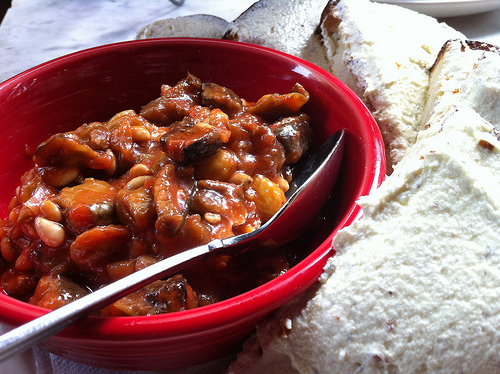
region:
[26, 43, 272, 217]
A red bowl filled with food.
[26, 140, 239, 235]
Food of choice appears to be chili.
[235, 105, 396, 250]
A silver spoon inside a red bowl.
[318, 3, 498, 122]
Slices of bread next to red bowl.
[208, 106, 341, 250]
A silver spoon resting ontop of food.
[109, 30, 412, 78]
A red bowl with white bread for contrast.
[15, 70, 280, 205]
A bowl filled with comfort food.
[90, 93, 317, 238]
A bowl filled with food that is not consumed.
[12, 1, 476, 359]
a spoon in a bowl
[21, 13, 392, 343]
a red bowl with food in it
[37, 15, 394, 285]
a bowl of food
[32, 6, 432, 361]
beans in a bowl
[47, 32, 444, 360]
a silver spoon in a bowl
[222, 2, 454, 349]
food on the side of a bowl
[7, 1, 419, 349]
a bowl on a table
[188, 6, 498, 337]
lots of bread near a bowl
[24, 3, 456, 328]
a bean soup in a bowl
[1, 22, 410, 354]
MEAT DISH IN RED BOWL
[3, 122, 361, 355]
LARGE SPOON IN MAIN DISH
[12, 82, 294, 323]
BEEF STEW IN BOWL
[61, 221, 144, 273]
CARROT IN STEW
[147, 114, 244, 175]
MEAT IN STEW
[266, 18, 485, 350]
MULTIPLE BREAD ITEMS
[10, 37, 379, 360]
GLASS BOWL FOR SERVING FOOD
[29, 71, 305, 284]
SAUCE IN STEW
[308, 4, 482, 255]
SANDWICHES CUT INTO TRIANGLES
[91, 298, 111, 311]
part of a spoon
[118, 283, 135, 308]
edge of a spoon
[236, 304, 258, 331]
part of a bowl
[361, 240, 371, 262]
part of a cloth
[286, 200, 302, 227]
part of a spoon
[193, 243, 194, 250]
edge of a spoon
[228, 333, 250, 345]
side of a bowl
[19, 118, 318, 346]
the metal silver spoon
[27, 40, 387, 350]
the deep red bowl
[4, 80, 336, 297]
the chili in the red bowl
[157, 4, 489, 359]
the bread laying next to the bowl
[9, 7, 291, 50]
the table the stuff is sitting on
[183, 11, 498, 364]
the toasted bread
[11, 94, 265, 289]
the vegtables in the chili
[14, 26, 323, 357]
the bowl and spoon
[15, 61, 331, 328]
the food in the red bowl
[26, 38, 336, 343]
the round bowl with food in it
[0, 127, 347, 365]
A long silver spoon.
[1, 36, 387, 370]
A round red bowl.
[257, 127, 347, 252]
An oval silver spoon end.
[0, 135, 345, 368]
spoon resting on its side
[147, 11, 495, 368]
slices of bread arranged around plate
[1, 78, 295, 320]
thick chilli or stew